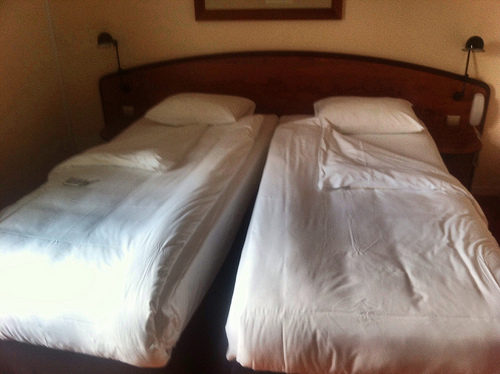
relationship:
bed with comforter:
[0, 67, 275, 341] [74, 119, 177, 174]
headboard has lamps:
[125, 48, 468, 123] [450, 11, 499, 99]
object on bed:
[56, 169, 83, 195] [0, 67, 275, 341]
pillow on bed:
[315, 72, 439, 160] [0, 67, 275, 341]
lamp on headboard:
[89, 16, 126, 60] [125, 48, 468, 123]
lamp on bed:
[89, 16, 126, 60] [0, 67, 275, 341]